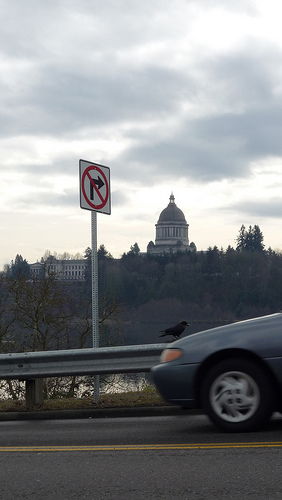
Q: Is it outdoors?
A: Yes, it is outdoors.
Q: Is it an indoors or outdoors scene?
A: It is outdoors.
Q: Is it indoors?
A: No, it is outdoors.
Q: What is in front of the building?
A: The trees are in front of the building.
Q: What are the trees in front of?
A: The trees are in front of the building.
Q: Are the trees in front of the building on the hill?
A: Yes, the trees are in front of the building.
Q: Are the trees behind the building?
A: No, the trees are in front of the building.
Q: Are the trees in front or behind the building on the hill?
A: The trees are in front of the building.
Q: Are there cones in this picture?
A: No, there are no cones.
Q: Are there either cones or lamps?
A: No, there are no cones or lamps.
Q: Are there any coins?
A: No, there are no coins.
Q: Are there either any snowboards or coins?
A: No, there are no coins or snowboards.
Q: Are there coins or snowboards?
A: No, there are no coins or snowboards.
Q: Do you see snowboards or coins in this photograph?
A: No, there are no coins or snowboards.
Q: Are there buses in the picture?
A: No, there are no buses.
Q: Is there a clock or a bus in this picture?
A: No, there are no buses or clocks.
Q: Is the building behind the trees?
A: Yes, the building is behind the trees.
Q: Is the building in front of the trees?
A: No, the building is behind the trees.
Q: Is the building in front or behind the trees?
A: The building is behind the trees.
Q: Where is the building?
A: The building is on the hill.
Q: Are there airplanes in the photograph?
A: No, there are no airplanes.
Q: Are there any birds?
A: Yes, there is a bird.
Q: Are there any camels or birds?
A: Yes, there is a bird.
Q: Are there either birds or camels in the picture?
A: Yes, there is a bird.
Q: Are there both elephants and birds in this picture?
A: No, there is a bird but no elephants.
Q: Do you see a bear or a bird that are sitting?
A: Yes, the bird is sitting.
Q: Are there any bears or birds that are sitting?
A: Yes, the bird is sitting.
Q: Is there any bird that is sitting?
A: Yes, there is a bird that is sitting.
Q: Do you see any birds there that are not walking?
A: Yes, there is a bird that is sitting .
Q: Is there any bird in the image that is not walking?
A: Yes, there is a bird that is sitting.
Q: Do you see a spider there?
A: No, there are no spiders.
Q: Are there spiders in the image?
A: No, there are no spiders.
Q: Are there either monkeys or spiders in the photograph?
A: No, there are no spiders or monkeys.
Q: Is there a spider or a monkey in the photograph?
A: No, there are no spiders or monkeys.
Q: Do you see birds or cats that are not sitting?
A: No, there is a bird but it is sitting.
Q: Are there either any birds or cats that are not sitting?
A: No, there is a bird but it is sitting.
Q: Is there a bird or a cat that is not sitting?
A: No, there is a bird but it is sitting.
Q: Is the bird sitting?
A: Yes, the bird is sitting.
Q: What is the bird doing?
A: The bird is sitting.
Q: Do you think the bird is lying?
A: No, the bird is sitting.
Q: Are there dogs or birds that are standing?
A: No, there is a bird but it is sitting.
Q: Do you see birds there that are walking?
A: No, there is a bird but it is sitting.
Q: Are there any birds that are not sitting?
A: No, there is a bird but it is sitting.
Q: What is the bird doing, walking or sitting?
A: The bird is sitting.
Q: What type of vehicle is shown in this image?
A: The vehicle is a car.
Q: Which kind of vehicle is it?
A: The vehicle is a car.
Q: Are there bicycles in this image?
A: No, there are no bicycles.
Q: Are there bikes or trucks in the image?
A: No, there are no bikes or trucks.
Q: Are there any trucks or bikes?
A: No, there are no bikes or trucks.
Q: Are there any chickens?
A: No, there are no chickens.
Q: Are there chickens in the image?
A: No, there are no chickens.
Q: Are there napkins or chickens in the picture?
A: No, there are no chickens or napkins.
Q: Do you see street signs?
A: Yes, there is a street sign.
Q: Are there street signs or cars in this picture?
A: Yes, there is a street sign.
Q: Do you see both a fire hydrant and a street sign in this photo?
A: No, there is a street sign but no fire hydrants.